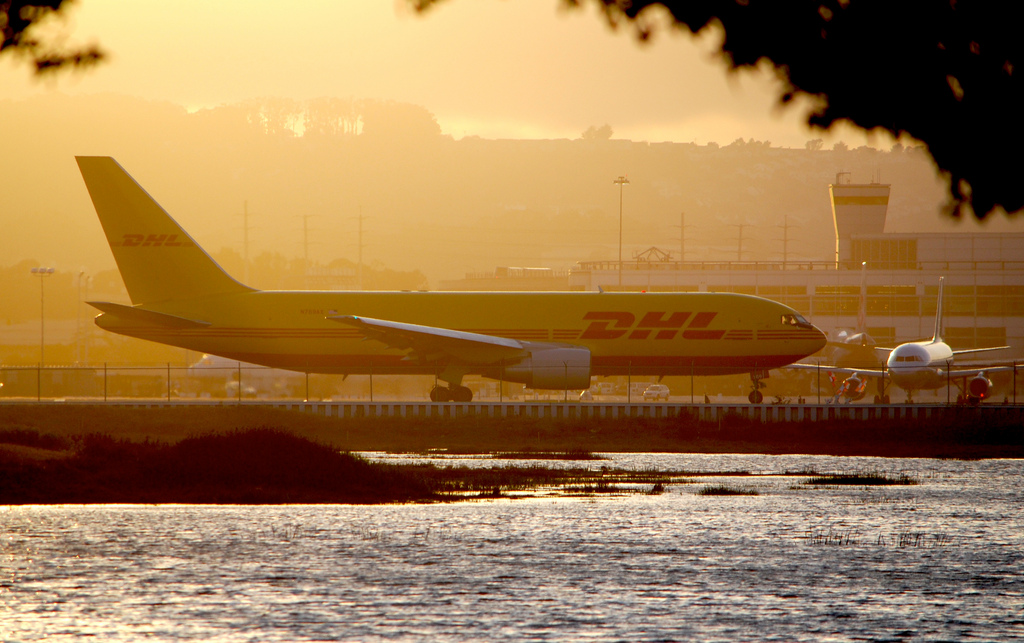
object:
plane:
[76, 156, 827, 402]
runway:
[2, 395, 1024, 403]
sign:
[580, 311, 727, 340]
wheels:
[430, 386, 473, 402]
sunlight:
[0, 505, 1024, 578]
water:
[0, 448, 1024, 643]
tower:
[829, 169, 892, 270]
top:
[577, 252, 1024, 270]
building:
[569, 168, 1024, 396]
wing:
[323, 314, 592, 389]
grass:
[0, 424, 918, 506]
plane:
[781, 275, 1024, 406]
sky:
[0, 0, 1024, 152]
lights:
[30, 267, 55, 277]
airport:
[2, 156, 1024, 440]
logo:
[109, 234, 194, 247]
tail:
[74, 156, 261, 306]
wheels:
[748, 390, 764, 405]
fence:
[0, 355, 1024, 407]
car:
[643, 384, 671, 402]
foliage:
[0, 0, 1024, 226]